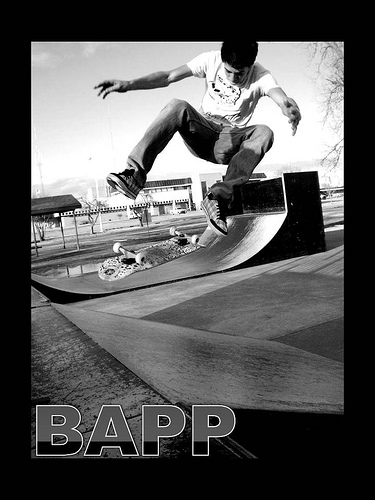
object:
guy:
[92, 40, 301, 237]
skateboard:
[97, 224, 201, 283]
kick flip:
[93, 39, 301, 283]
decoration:
[35, 404, 236, 455]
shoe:
[200, 194, 228, 237]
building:
[106, 176, 195, 223]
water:
[41, 263, 98, 280]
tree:
[302, 42, 342, 180]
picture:
[30, 40, 344, 458]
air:
[30, 42, 94, 193]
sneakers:
[198, 190, 228, 236]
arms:
[124, 51, 204, 89]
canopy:
[30, 194, 83, 216]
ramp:
[49, 301, 343, 416]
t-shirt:
[185, 49, 281, 127]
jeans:
[127, 99, 274, 200]